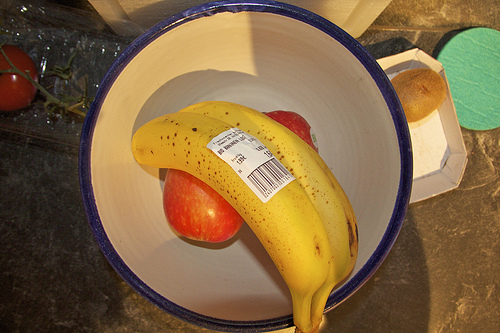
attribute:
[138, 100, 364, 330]
bananas — in the picture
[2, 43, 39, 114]
tomato — in the picture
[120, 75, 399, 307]
bananas — in the picture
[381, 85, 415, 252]
blue rim — in the picture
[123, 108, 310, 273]
apple — in the picture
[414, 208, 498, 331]
marble — gray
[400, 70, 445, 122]
kiwi — in the picture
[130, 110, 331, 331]
banana — in the picture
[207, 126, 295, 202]
sticker — in the picture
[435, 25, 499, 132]
disk — green